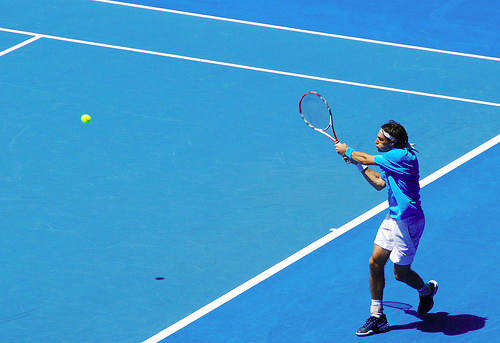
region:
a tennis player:
[305, 69, 370, 216]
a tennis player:
[376, 84, 439, 334]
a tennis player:
[326, 63, 436, 291]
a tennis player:
[362, 82, 414, 268]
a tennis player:
[346, 48, 395, 288]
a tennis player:
[356, 108, 403, 332]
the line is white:
[222, 280, 235, 316]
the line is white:
[194, 278, 215, 303]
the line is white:
[211, 290, 226, 307]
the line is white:
[194, 290, 221, 333]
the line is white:
[212, 300, 220, 304]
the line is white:
[202, 302, 217, 328]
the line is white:
[209, 305, 215, 307]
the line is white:
[211, 303, 221, 305]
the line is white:
[192, 313, 202, 335]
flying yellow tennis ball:
[78, 113, 91, 122]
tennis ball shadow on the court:
[155, 275, 165, 282]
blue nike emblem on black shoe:
[375, 320, 385, 327]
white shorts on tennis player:
[371, 207, 426, 263]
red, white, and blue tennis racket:
[298, 90, 350, 165]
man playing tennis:
[334, 118, 438, 337]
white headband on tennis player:
[380, 120, 416, 152]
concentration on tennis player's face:
[374, 122, 409, 154]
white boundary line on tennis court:
[163, 6, 498, 63]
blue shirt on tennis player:
[371, 150, 423, 220]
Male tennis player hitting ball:
[335, 117, 440, 334]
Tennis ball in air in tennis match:
[76, 108, 95, 127]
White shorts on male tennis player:
[370, 210, 425, 262]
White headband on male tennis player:
[375, 125, 410, 141]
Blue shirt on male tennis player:
[375, 145, 425, 216]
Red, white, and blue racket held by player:
[296, 88, 339, 157]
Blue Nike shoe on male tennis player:
[351, 315, 386, 335]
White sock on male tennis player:
[367, 292, 382, 317]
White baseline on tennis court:
[132, 130, 494, 340]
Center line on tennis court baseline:
[321, 220, 341, 238]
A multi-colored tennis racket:
[290, 86, 346, 143]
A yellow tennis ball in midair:
[68, 103, 94, 132]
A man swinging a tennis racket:
[292, 84, 462, 336]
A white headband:
[377, 121, 414, 145]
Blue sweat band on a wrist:
[340, 137, 355, 164]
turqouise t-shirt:
[369, 146, 444, 227]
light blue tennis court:
[97, 14, 290, 340]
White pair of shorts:
[382, 198, 429, 273]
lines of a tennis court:
[209, 10, 499, 94]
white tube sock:
[365, 295, 388, 317]